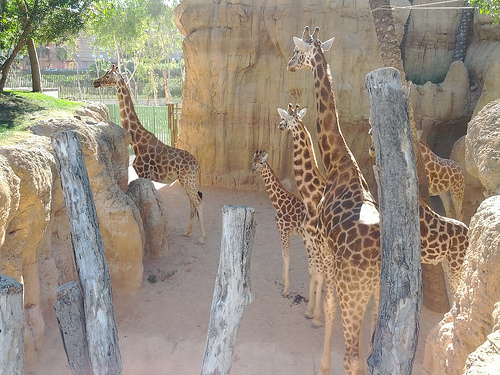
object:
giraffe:
[281, 26, 379, 375]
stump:
[357, 66, 427, 375]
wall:
[176, 2, 497, 206]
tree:
[0, 2, 98, 95]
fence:
[111, 106, 179, 157]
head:
[285, 25, 336, 73]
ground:
[30, 175, 443, 372]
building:
[21, 36, 114, 71]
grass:
[0, 90, 82, 146]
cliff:
[0, 88, 170, 366]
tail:
[193, 164, 204, 203]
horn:
[302, 25, 311, 40]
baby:
[249, 151, 320, 296]